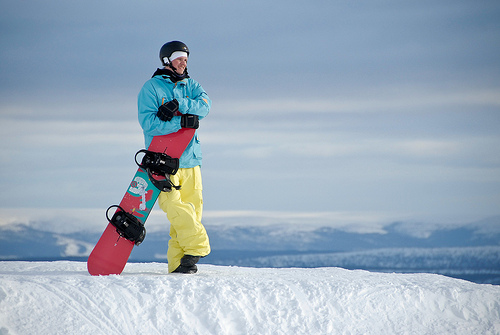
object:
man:
[137, 40, 210, 275]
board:
[87, 112, 200, 276]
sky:
[0, 0, 499, 223]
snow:
[0, 259, 499, 334]